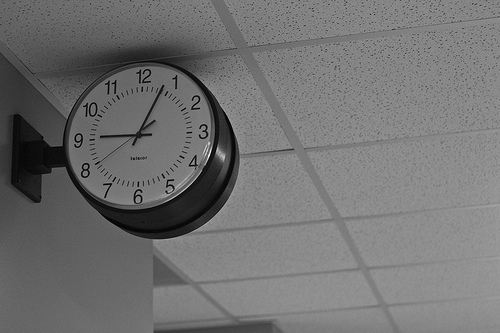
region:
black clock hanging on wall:
[17, 43, 276, 258]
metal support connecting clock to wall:
[1, 107, 76, 199]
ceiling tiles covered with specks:
[220, 11, 471, 181]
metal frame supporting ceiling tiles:
[226, 15, 441, 310]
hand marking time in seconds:
[46, 136, 142, 192]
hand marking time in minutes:
[130, 70, 171, 141]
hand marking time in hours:
[86, 125, 156, 142]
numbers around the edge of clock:
[60, 51, 225, 216]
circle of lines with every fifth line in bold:
[81, 76, 205, 201]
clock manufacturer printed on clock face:
[115, 150, 170, 166]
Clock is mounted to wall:
[10, 59, 240, 249]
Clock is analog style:
[59, 58, 219, 218]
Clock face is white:
[69, 65, 209, 204]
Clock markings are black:
[72, 67, 207, 204]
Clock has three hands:
[88, 80, 184, 180]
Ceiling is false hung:
[1, 0, 499, 332]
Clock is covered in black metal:
[13, 64, 239, 239]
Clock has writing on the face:
[125, 150, 157, 165]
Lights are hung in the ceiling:
[149, 244, 187, 291]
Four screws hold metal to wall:
[10, 106, 54, 213]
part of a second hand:
[105, 140, 128, 158]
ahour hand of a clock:
[90, 130, 145, 135]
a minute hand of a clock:
[142, 77, 163, 129]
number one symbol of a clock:
[167, 67, 181, 87]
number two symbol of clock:
[188, 89, 198, 111]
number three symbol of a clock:
[192, 114, 207, 139]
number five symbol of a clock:
[162, 169, 172, 192]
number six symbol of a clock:
[123, 190, 148, 203]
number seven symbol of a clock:
[93, 172, 112, 198]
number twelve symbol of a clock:
[131, 64, 151, 85]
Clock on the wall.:
[54, 50, 274, 258]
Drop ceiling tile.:
[309, 79, 451, 216]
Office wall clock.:
[43, 45, 301, 249]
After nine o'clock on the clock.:
[59, 60, 309, 215]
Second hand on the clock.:
[91, 146, 153, 180]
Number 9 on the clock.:
[72, 128, 87, 149]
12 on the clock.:
[133, 57, 156, 97]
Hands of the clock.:
[89, 92, 216, 185]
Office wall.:
[22, 208, 134, 306]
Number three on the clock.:
[193, 105, 219, 176]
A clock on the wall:
[6, 65, 251, 250]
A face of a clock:
[56, 60, 222, 220]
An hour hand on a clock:
[91, 127, 166, 157]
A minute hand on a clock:
[141, 78, 168, 143]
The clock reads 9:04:
[66, 61, 221, 210]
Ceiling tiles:
[245, 7, 497, 300]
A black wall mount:
[13, 114, 61, 209]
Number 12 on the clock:
[128, 65, 160, 101]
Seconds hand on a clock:
[91, 137, 130, 169]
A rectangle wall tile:
[307, 136, 499, 207]